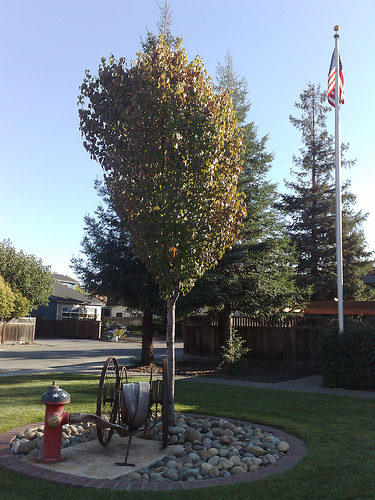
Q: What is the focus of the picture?
A: A small tree with green leaves.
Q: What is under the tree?
A: Rocks, a fire hydrant, and a machine.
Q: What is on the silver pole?
A: An American flag.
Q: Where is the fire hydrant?
A: Under the tree.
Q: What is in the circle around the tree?
A: Large boulders.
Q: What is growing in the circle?
A: The medium sized tree.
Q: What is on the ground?
A: Low cut green grass.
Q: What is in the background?
A: The pine tree.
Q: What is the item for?
A: Winding up a hose.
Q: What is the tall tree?
A: Green.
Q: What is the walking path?
A: Grey.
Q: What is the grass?
A: Short and green.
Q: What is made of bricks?
A: The rim.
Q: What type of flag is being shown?
A: U.S. Flag.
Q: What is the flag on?
A: A flagpole.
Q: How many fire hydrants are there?
A: One.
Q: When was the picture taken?
A: Daytime.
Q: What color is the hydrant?
A: Red.